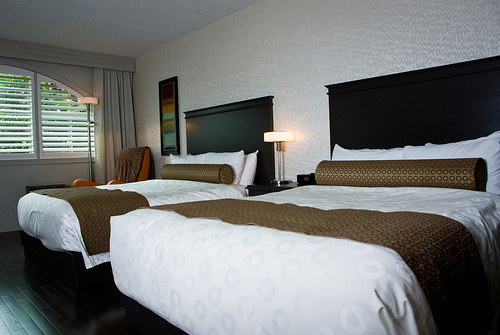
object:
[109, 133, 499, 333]
bed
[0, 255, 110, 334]
floor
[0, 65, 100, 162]
window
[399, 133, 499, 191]
pillow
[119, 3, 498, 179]
wall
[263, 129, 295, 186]
lamp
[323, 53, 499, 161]
headboard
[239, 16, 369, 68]
design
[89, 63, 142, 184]
curtain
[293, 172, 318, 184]
clock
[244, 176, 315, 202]
nightstand